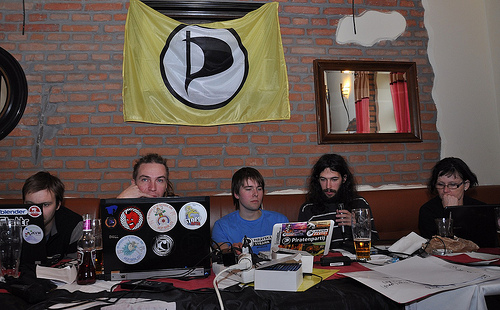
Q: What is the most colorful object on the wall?
A: A flag.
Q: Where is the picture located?
A: On the wall.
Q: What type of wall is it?
A: Brick wall.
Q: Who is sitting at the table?
A: A group of people.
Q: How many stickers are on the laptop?
A: Six.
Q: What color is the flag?
A: Yellow and black.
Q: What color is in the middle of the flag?
A: Black and white.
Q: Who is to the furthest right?
A: A female.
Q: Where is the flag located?
A: Above the people's head.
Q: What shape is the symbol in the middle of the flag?
A: Circular.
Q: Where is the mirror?
A: Against the brick wall.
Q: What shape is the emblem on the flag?
A: Circle.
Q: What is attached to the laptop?
A: Logos.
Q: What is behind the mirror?
A: A brick wall.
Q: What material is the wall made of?
A: Brick.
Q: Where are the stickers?
A: On the laptop.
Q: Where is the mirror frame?
A: Surrounding the mirror.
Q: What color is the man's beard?
A: Brown.